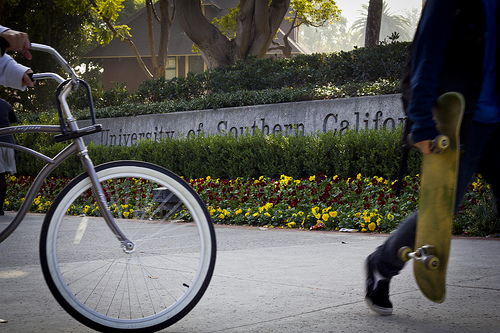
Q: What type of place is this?
A: It is a sidewalk.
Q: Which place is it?
A: It is a sidewalk.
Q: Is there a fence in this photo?
A: No, there are no fences.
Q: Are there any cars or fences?
A: No, there are no fences or cars.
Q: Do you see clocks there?
A: No, there are no clocks.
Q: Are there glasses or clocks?
A: No, there are no clocks or glasses.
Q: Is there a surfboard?
A: No, there are no surfboards.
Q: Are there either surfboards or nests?
A: No, there are no surfboards or nests.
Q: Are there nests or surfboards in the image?
A: No, there are no surfboards or nests.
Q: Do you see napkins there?
A: No, there are no napkins.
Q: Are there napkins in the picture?
A: No, there are no napkins.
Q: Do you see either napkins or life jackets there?
A: No, there are no napkins or life jackets.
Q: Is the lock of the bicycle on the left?
A: Yes, the lock is on the left of the image.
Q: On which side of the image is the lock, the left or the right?
A: The lock is on the left of the image.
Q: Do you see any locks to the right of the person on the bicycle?
A: Yes, there is a lock to the right of the person.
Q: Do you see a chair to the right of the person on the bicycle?
A: No, there is a lock to the right of the person.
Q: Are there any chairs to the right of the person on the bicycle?
A: No, there is a lock to the right of the person.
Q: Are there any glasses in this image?
A: No, there are no glasses.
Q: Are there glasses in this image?
A: No, there are no glasses.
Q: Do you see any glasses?
A: No, there are no glasses.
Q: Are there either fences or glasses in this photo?
A: No, there are no glasses or fences.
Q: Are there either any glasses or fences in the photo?
A: No, there are no glasses or fences.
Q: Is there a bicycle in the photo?
A: Yes, there is a bicycle.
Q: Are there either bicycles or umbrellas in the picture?
A: Yes, there is a bicycle.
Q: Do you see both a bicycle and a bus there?
A: No, there is a bicycle but no buses.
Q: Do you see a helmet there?
A: No, there are no helmets.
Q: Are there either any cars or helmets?
A: No, there are no helmets or cars.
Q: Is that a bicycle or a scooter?
A: That is a bicycle.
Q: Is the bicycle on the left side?
A: Yes, the bicycle is on the left of the image.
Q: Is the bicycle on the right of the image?
A: No, the bicycle is on the left of the image.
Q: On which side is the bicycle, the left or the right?
A: The bicycle is on the left of the image.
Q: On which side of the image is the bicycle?
A: The bicycle is on the left of the image.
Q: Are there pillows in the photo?
A: No, there are no pillows.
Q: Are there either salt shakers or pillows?
A: No, there are no pillows or salt shakers.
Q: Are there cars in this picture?
A: No, there are no cars.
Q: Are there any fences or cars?
A: No, there are no cars or fences.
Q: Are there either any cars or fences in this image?
A: No, there are no cars or fences.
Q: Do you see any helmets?
A: No, there are no helmets.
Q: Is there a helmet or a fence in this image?
A: No, there are no helmets or fences.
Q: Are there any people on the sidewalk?
A: Yes, there is a person on the sidewalk.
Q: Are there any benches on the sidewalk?
A: No, there is a person on the sidewalk.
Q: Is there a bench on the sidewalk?
A: No, there is a person on the sidewalk.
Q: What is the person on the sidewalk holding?
A: The person is holding the skateboard.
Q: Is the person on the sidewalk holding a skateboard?
A: Yes, the person is holding a skateboard.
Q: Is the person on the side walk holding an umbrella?
A: No, the person is holding a skateboard.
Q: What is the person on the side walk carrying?
A: The person is carrying a skateboard.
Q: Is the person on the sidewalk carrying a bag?
A: No, the person is carrying a skateboard.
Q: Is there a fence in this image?
A: No, there are no fences.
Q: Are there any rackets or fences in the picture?
A: No, there are no fences or rackets.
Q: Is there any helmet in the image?
A: No, there are no helmets.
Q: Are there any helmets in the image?
A: No, there are no helmets.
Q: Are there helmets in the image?
A: No, there are no helmets.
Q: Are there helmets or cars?
A: No, there are no helmets or cars.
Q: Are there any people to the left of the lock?
A: Yes, there is a person to the left of the lock.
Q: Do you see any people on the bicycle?
A: Yes, there is a person on the bicycle.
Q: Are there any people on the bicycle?
A: Yes, there is a person on the bicycle.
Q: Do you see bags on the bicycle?
A: No, there is a person on the bicycle.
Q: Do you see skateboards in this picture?
A: Yes, there is a skateboard.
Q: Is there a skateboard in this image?
A: Yes, there is a skateboard.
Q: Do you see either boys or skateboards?
A: Yes, there is a skateboard.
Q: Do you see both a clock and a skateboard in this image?
A: No, there is a skateboard but no clocks.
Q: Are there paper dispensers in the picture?
A: No, there are no paper dispensers.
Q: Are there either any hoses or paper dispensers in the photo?
A: No, there are no paper dispensers or hoses.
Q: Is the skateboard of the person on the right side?
A: Yes, the skateboard is on the right of the image.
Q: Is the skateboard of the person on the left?
A: No, the skateboard is on the right of the image.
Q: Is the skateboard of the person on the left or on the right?
A: The skateboard is on the right of the image.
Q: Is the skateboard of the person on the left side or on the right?
A: The skateboard is on the right of the image.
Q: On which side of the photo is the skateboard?
A: The skateboard is on the right of the image.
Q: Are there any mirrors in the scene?
A: No, there are no mirrors.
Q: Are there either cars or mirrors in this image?
A: No, there are no mirrors or cars.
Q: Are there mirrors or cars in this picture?
A: No, there are no mirrors or cars.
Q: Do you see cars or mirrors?
A: No, there are no mirrors or cars.